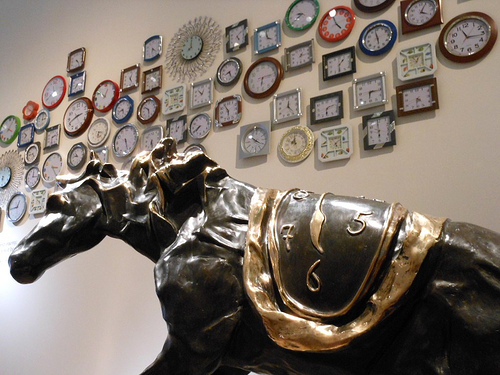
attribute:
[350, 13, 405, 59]
clock — blue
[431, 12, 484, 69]
clock — brown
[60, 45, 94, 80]
clock — square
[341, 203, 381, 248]
5 — number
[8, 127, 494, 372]
horse — fake, wooden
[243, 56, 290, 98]
clock — round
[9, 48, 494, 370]
wall — white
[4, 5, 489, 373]
wall — white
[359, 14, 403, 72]
clock — blue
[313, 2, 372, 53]
clock — orange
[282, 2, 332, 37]
clock — green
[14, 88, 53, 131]
clock — flower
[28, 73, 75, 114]
clock — white, analog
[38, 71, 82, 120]
frame — red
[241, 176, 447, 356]
clock — melted clock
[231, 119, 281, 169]
clock — silver, square, framed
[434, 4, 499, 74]
clock — circular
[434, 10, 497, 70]
frame — wood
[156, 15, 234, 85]
clock — shiny sun shaped , analog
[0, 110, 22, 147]
clock — analog, white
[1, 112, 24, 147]
frame — green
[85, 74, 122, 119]
clock — white, analog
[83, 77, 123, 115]
frame — red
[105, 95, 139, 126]
frame — blue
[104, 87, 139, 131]
clock — white, analog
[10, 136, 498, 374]
sculpture — horse, wooden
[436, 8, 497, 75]
clock — brown, circular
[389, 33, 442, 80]
clock — square, bizare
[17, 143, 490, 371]
statue — shiny, bronze, large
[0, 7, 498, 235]
clocks — many, small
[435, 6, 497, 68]
clock — round